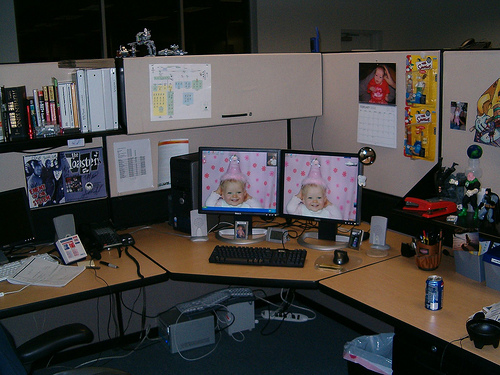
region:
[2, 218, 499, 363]
Yellow wood desk in the room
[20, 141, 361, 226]
Monitors on the desk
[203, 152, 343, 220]
Baby pictures on the monitors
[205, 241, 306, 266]
Black keyboard on the desk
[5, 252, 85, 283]
Notebook on the desk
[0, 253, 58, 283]
White keyboard on the desk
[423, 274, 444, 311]
Cola can on the desk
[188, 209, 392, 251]
Speakers on the desk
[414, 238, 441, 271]
Pen holder on the desk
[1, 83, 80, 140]
Books on the shelf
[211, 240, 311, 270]
BLACK KEYBOARD FOR COMPUTER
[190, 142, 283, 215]
SINGLE SCREEN FOR COMPUTER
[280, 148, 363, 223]
SINGLE SCREEN FOR COMPUTER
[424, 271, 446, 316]
SOFT DRINK CAN ON TABLE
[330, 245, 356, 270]
WIRELESS MOUSE ON PAD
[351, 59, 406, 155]
COLORFUL CALENDAR ON WALL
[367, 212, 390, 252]
GRAY COMPUTER SPEAKER ON TABLE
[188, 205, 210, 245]
GRAY COMPUTER SPEAKER ON TABLE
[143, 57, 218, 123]
WORK SPREAD SHEET ON BOARD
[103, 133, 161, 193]
TELEPHONE LIST ON BOARD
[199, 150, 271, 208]
the screen is on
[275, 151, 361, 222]
he screen is on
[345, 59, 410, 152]
calendar on the wall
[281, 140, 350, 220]
monitor for the computer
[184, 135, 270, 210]
monitor of the computer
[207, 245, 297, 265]
keyboard for the computer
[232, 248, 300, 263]
the keyboard is black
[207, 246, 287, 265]
keyboard on the desk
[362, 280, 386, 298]
the desk is wood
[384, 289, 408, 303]
the desk is tan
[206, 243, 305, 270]
a black computer keyboard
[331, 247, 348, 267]
a black computer mouse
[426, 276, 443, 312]
a blue can of soda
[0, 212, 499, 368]
a brown wood corner desk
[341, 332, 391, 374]
a lined trash can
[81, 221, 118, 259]
a black telephone handset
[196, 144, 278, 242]
a small computer monitor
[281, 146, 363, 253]
a small computer monitor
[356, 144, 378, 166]
a small rearview mirror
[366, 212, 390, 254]
a small grey speaker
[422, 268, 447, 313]
Can on a desk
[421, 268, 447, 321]
Can is on a desk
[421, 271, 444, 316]
Aluminum can on a desk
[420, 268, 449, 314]
Aluminum can is on a desk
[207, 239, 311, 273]
Keyboard on a desk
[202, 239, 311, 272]
Keyboard is on a desk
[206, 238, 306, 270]
Black keyboard on a desk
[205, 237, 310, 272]
Black keyboard is on a desk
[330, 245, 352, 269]
Mouse on a desk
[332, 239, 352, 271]
Mouse is on a desk